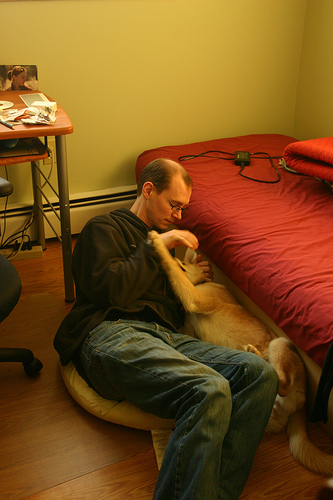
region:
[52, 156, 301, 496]
A man and his dog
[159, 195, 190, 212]
A man's eye glasses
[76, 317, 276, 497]
A man's blue jeans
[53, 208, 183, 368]
A man's black sweatshirt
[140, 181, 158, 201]
A man's right ear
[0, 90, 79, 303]
A stained wooden desk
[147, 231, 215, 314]
A dog's left front leg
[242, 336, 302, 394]
A dog's left rear leg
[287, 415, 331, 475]
A dog's tail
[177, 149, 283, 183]
A black electrical cord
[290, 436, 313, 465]
the dogs tail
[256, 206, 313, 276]
a red comforter on the bed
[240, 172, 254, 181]
a black cord on the bed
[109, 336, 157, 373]
the man is wearing blue jeans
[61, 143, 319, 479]
a man playing with a dog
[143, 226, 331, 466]
a large brown and white dog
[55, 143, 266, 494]
a man sitting down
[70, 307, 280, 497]
a pair of jeans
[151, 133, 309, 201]
a computer charger laying on a bed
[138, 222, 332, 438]
a dog touching a hand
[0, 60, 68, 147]
a picture on a desk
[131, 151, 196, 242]
a man with glasses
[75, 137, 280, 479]
a man petting a dog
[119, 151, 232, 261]
a balding man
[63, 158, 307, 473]
Man and dog on the floor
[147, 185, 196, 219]
Glasses on the man's face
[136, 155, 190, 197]
The man is balding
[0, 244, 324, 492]
The floor is made of wood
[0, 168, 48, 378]
Office chair on wheels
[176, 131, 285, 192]
Electrical cord on the bed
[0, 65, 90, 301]
A desk against the wall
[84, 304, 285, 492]
Jeans on the man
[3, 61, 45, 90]
Photo of a woman on the desk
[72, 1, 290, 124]
the beige painted wall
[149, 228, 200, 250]
the man's right hand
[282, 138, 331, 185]
red blanket on bed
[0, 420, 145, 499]
floor made of wood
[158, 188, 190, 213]
glasses on the man's face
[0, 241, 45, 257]
surge protector on floor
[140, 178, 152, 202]
the man's right ear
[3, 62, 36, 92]
picture of woman on desk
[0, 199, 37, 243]
wires from surge protector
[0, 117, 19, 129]
pen on the desk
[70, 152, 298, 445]
man petting large brown dog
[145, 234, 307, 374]
large brown dog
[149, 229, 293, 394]
large brown dog lying near man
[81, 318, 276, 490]
blue jeans worn by man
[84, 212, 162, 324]
black shirt worn by man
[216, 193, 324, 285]
red sheet on bed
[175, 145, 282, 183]
laptop charger on the bed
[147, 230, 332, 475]
a dog laying down on the floor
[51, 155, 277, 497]
man laying down on the ground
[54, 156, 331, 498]
man and his dog on the floor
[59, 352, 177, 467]
a dog bed underneath the man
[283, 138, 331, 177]
a folded red blanket on the ground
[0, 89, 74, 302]
a messy computer desk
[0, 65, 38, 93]
picture of a woman on the desk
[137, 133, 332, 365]
crumpled red sheet on the bed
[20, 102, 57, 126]
crumpled paper on the table